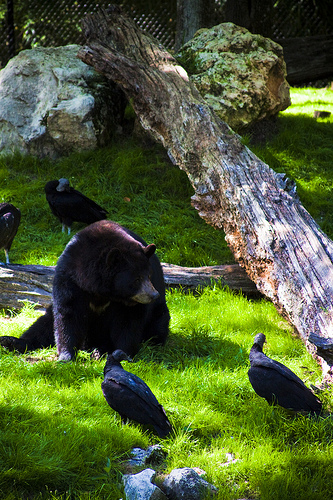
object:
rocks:
[116, 442, 216, 499]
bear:
[52, 219, 172, 364]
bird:
[247, 333, 323, 420]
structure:
[0, 261, 54, 315]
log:
[74, 4, 333, 387]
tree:
[74, 0, 332, 387]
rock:
[172, 21, 291, 134]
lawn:
[0, 369, 333, 499]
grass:
[0, 84, 333, 499]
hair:
[118, 243, 157, 269]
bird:
[100, 349, 177, 443]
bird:
[41, 178, 110, 236]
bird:
[0, 195, 21, 267]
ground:
[1, 88, 333, 499]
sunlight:
[174, 402, 233, 463]